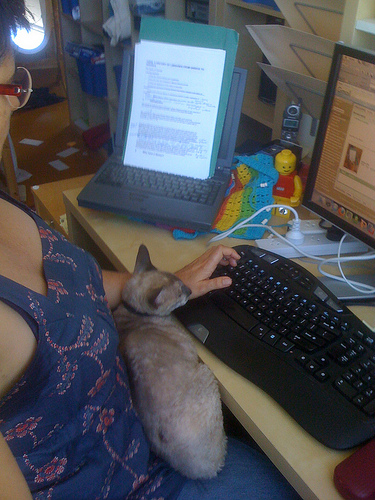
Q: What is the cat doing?
A: Looking at the monitor.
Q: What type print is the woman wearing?
A: Floral.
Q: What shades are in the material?
A: Blue , red, yellow, light blue.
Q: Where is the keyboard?
A: On the desk.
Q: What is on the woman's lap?
A: Cat.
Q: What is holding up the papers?
A: Laptop screen and keypad.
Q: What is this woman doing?
A: Typing on computer keyboard.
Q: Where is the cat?
A: On woman's lap.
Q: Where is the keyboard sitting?
A: On desk.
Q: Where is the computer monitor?
A: Near the keyboard.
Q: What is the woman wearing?
A: A flowery blue tank top.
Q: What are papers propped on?
A: A laptop.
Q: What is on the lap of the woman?
A: A cat.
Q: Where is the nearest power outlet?
A: A surge protector on the table.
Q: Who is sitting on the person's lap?
A: Cat.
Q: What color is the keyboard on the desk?
A: Black.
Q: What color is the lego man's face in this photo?
A: Yellow.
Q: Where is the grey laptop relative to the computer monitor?
A: Left.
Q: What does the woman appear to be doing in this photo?
A: Typing.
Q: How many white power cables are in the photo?
A: One.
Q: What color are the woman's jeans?
A: Blue.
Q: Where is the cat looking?
A: Towards monitor.